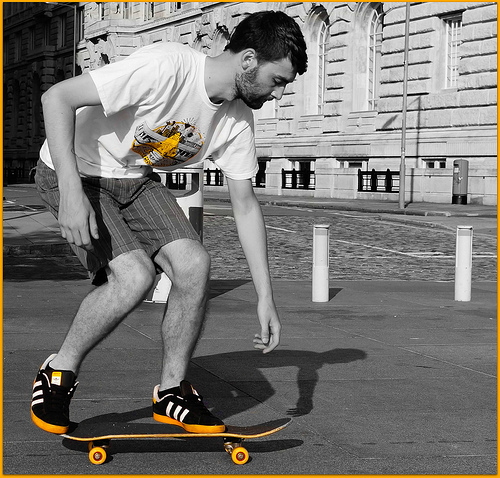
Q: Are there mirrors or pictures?
A: No, there are no mirrors or pictures.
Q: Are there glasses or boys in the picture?
A: No, there are no boys or glasses.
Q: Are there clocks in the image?
A: No, there are no clocks.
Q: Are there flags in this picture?
A: No, there are no flags.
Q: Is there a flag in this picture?
A: No, there are no flags.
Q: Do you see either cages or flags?
A: No, there are no flags or cages.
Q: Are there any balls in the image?
A: No, there are no balls.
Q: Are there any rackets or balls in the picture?
A: No, there are no balls or rackets.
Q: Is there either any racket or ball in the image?
A: No, there are no balls or rackets.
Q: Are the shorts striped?
A: Yes, the shorts are striped.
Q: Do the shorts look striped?
A: Yes, the shorts are striped.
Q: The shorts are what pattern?
A: The shorts are striped.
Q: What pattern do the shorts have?
A: The shorts have striped pattern.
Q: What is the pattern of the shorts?
A: The shorts are striped.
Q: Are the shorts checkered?
A: No, the shorts are striped.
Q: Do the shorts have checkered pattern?
A: No, the shorts are striped.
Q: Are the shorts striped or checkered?
A: The shorts are striped.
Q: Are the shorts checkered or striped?
A: The shorts are striped.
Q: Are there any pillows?
A: No, there are no pillows.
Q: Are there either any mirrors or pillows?
A: No, there are no pillows or mirrors.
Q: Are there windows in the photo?
A: Yes, there is a window.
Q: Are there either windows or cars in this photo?
A: Yes, there is a window.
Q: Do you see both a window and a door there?
A: No, there is a window but no doors.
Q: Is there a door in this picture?
A: No, there are no doors.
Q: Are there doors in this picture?
A: No, there are no doors.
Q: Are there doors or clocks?
A: No, there are no doors or clocks.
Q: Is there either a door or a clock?
A: No, there are no doors or clocks.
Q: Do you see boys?
A: No, there are no boys.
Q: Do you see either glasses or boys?
A: No, there are no boys or glasses.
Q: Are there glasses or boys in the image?
A: No, there are no boys or glasses.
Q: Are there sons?
A: No, there are no sons.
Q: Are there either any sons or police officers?
A: No, there are no sons or police officers.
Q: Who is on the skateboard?
A: The guy is on the skateboard.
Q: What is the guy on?
A: The guy is on the skateboard.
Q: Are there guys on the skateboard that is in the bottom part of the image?
A: Yes, there is a guy on the skateboard.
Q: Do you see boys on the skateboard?
A: No, there is a guy on the skateboard.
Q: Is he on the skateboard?
A: Yes, the guy is on the skateboard.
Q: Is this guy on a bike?
A: No, the guy is on the skateboard.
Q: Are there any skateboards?
A: Yes, there is a skateboard.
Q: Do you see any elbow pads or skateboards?
A: Yes, there is a skateboard.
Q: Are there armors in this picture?
A: No, there are no armors.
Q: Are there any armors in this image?
A: No, there are no armors.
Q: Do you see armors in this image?
A: No, there are no armors.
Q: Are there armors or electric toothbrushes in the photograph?
A: No, there are no armors or electric toothbrushes.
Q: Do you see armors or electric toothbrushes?
A: No, there are no armors or electric toothbrushes.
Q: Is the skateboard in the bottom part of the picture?
A: Yes, the skateboard is in the bottom of the image.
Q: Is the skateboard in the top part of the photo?
A: No, the skateboard is in the bottom of the image.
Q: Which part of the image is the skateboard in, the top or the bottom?
A: The skateboard is in the bottom of the image.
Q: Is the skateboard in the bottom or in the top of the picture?
A: The skateboard is in the bottom of the image.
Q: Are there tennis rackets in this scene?
A: No, there are no tennis rackets.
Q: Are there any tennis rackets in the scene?
A: No, there are no tennis rackets.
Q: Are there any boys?
A: No, there are no boys.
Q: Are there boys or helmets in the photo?
A: No, there are no boys or helmets.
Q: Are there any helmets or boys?
A: No, there are no boys or helmets.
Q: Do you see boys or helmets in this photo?
A: No, there are no boys or helmets.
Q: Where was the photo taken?
A: It was taken at the sidewalk.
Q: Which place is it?
A: It is a sidewalk.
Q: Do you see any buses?
A: No, there are no buses.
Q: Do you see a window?
A: Yes, there is a window.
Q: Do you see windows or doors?
A: Yes, there is a window.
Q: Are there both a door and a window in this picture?
A: No, there is a window but no doors.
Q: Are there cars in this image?
A: No, there are no cars.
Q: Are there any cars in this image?
A: No, there are no cars.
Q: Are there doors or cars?
A: No, there are no cars or doors.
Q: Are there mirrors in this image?
A: No, there are no mirrors.